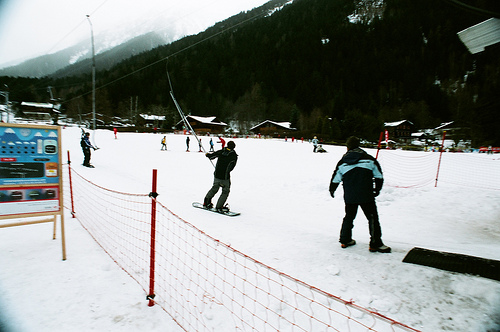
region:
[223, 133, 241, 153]
the head of a man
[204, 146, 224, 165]
the arm of a man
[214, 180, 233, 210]
the leg of a man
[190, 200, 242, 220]
a snowboard under the man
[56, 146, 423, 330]
a red mesh fence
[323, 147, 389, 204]
a black and blue coat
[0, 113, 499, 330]
white snow on the ground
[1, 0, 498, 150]
green trees on the mountain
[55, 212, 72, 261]
a brown wooden board leg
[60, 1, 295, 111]
wires in the air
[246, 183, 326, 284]
The snow is white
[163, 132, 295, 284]
The people are skiing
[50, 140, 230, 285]
The fence is red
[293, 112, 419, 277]
The person has a coat on it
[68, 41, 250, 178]
The people are in the snow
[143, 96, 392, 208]
Buildings are in the back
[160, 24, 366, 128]
The trees have green leaves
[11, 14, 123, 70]
The sky is cloudy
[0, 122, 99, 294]
The sign is square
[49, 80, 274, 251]
The people have ski poles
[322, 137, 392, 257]
a man standing on snow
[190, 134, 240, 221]
man riding on snowboard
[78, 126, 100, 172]
man riding on snowboard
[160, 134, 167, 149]
man riding on snowboard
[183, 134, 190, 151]
man riding on snowboard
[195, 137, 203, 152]
man riding on snowboard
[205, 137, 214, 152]
man riding on snowboard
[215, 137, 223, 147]
man riding on snowboard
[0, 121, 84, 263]
an informational sign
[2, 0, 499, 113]
a large snow capped mountain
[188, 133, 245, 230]
A man is standing on a snowboard.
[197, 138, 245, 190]
A man is wearing a dark top.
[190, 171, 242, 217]
A man is wearing gray pants.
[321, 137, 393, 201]
A man is wearing a blue and black top.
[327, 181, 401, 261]
A man is wearing dark pants.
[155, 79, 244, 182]
A snowboarder is holding an object in his hands.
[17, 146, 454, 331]
The color of a fence is red.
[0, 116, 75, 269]
A sign has the colors of blue, red, yellow, and white.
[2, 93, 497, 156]
Houses are in the background.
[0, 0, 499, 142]
Mountains are in the background.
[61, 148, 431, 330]
THE SAFETY NET IS RED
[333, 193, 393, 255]
THE MAN IS WEARING BLACK PANTS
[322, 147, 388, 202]
THE MAN IS WEARING A BLACK AND BLUE JACKET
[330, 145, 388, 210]
THE MAN'S JACKET HAS A HOOD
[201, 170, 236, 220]
THE MAN IS WEARING GREY PANTS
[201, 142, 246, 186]
THE MAN IS WEARING A BLACK JACKET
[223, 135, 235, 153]
THE MAN IS WEARING A BLACK HAT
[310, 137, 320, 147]
THE WOMAN IS WEARING A BLUE JACKET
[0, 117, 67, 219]
THE SIGN IS BLUE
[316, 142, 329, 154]
ONE PERSON IS SITTING ON THE SNOW